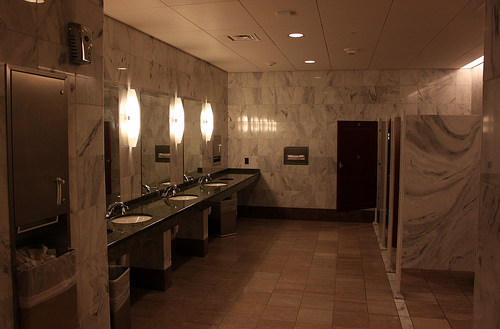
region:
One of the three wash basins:
[110, 214, 150, 222]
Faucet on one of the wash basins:
[106, 194, 128, 218]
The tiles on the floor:
[108, 218, 474, 327]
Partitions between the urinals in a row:
[379, 115, 477, 271]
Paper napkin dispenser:
[284, 146, 310, 164]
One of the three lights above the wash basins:
[118, 85, 140, 147]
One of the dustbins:
[110, 266, 131, 327]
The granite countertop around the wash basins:
[107, 170, 253, 244]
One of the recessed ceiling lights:
[288, 32, 303, 38]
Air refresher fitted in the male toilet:
[67, 20, 92, 64]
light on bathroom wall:
[116, 70, 145, 157]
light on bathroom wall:
[169, 94, 197, 152]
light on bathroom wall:
[194, 101, 223, 141]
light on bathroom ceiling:
[286, 26, 302, 47]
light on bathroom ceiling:
[299, 53, 325, 72]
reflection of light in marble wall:
[231, 103, 252, 145]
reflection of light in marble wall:
[252, 114, 262, 141]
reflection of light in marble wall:
[266, 115, 280, 142]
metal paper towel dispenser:
[2, 56, 72, 232]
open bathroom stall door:
[337, 121, 382, 220]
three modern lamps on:
[120, 87, 212, 143]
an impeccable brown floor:
[255, 222, 377, 319]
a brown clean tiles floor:
[256, 251, 346, 316]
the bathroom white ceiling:
[180, 35, 480, 65]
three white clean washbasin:
[110, 175, 227, 220]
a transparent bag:
[21, 262, 72, 298]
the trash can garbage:
[16, 248, 73, 325]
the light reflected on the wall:
[235, 115, 276, 130]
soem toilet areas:
[383, 116, 473, 284]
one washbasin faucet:
[160, 179, 178, 199]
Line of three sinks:
[109, 165, 256, 240]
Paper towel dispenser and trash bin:
[6, 68, 83, 328]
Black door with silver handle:
[331, 114, 383, 222]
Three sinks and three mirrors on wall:
[104, 83, 259, 285]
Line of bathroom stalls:
[375, 108, 480, 294]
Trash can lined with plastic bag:
[213, 194, 243, 239]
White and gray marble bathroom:
[3, 5, 494, 322]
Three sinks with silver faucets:
[111, 167, 233, 231]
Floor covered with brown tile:
[112, 216, 497, 324]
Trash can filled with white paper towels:
[9, 243, 75, 325]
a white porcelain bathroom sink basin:
[112, 213, 151, 222]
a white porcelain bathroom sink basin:
[170, 194, 193, 198]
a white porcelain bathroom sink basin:
[206, 182, 226, 185]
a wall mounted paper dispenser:
[282, 145, 307, 164]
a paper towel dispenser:
[8, 68, 73, 233]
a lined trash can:
[15, 245, 76, 326]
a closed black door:
[337, 121, 373, 220]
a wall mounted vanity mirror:
[138, 90, 171, 196]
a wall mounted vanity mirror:
[107, 85, 121, 206]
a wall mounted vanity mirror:
[181, 95, 203, 173]